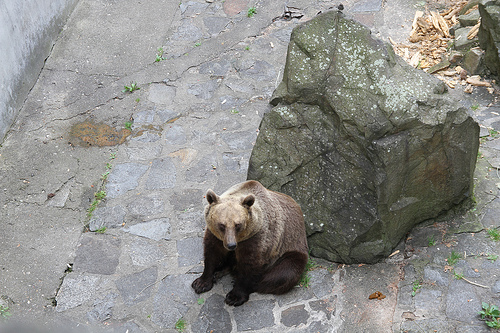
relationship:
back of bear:
[248, 174, 287, 215] [189, 204, 303, 318]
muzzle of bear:
[213, 218, 245, 245] [189, 204, 303, 318]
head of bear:
[217, 207, 266, 249] [197, 194, 388, 330]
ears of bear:
[204, 178, 260, 203] [189, 204, 303, 318]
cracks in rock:
[55, 167, 144, 295] [243, 7, 481, 269]